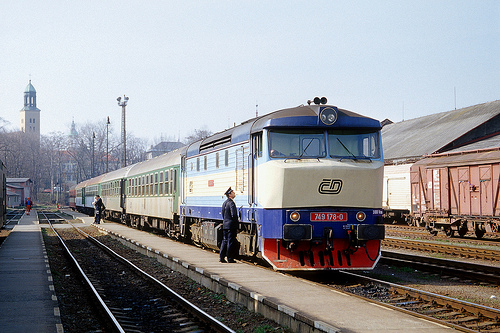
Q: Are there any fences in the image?
A: No, there are no fences.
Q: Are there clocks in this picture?
A: No, there are no clocks.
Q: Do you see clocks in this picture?
A: No, there are no clocks.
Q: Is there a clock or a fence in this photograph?
A: No, there are no clocks or fences.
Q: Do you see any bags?
A: No, there are no bags.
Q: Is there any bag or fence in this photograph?
A: No, there are no bags or fences.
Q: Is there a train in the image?
A: Yes, there is a train.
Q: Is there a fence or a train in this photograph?
A: Yes, there is a train.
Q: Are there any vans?
A: No, there are no vans.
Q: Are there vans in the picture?
A: No, there are no vans.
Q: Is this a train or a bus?
A: This is a train.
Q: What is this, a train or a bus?
A: This is a train.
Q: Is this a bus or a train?
A: This is a train.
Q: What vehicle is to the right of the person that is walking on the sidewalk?
A: The vehicle is a train.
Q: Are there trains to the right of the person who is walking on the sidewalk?
A: Yes, there is a train to the right of the person.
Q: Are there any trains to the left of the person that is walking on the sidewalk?
A: No, the train is to the right of the person.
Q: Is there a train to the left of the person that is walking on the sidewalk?
A: No, the train is to the right of the person.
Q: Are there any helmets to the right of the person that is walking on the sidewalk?
A: No, there is a train to the right of the person.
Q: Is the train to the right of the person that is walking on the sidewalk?
A: Yes, the train is to the right of the person.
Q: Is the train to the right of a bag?
A: No, the train is to the right of the person.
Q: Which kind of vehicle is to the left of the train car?
A: The vehicle is a train.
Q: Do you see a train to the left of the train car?
A: Yes, there is a train to the left of the train car.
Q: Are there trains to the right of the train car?
A: No, the train is to the left of the train car.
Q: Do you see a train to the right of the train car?
A: No, the train is to the left of the train car.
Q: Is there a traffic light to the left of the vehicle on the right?
A: No, there is a train to the left of the train car.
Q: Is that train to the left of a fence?
A: No, the train is to the left of the train car.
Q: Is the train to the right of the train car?
A: No, the train is to the left of the train car.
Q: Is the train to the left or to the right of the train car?
A: The train is to the left of the train car.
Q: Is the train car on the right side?
A: Yes, the train car is on the right of the image.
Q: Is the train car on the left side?
A: No, the train car is on the right of the image.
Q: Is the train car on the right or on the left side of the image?
A: The train car is on the right of the image.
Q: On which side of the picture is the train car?
A: The train car is on the right of the image.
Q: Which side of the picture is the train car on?
A: The train car is on the right of the image.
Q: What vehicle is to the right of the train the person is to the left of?
A: The vehicle is a train car.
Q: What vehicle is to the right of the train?
A: The vehicle is a train car.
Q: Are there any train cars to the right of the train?
A: Yes, there is a train car to the right of the train.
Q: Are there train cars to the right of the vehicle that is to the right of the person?
A: Yes, there is a train car to the right of the train.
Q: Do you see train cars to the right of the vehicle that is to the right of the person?
A: Yes, there is a train car to the right of the train.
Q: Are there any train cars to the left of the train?
A: No, the train car is to the right of the train.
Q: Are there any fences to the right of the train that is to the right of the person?
A: No, there is a train car to the right of the train.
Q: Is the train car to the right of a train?
A: Yes, the train car is to the right of a train.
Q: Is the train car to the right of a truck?
A: No, the train car is to the right of a train.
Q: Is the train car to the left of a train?
A: No, the train car is to the right of a train.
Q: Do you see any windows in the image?
A: Yes, there are windows.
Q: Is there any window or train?
A: Yes, there are windows.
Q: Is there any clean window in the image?
A: Yes, there are clean windows.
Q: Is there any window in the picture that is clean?
A: Yes, there are windows that are clean.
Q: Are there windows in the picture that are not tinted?
A: Yes, there are clean windows.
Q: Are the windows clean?
A: Yes, the windows are clean.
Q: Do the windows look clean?
A: Yes, the windows are clean.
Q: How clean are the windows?
A: The windows are clean.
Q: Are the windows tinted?
A: No, the windows are clean.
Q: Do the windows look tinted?
A: No, the windows are clean.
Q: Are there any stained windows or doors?
A: No, there are windows but they are clean.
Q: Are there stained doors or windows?
A: No, there are windows but they are clean.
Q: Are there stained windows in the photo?
A: No, there are windows but they are clean.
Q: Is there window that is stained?
A: No, there are windows but they are clean.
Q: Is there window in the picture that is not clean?
A: No, there are windows but they are clean.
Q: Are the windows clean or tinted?
A: The windows are clean.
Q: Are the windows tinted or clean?
A: The windows are clean.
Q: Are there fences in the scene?
A: No, there are no fences.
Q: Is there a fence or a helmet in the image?
A: No, there are no fences or helmets.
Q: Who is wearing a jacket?
A: The man is wearing a jacket.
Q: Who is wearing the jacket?
A: The man is wearing a jacket.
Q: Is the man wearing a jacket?
A: Yes, the man is wearing a jacket.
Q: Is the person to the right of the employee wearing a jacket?
A: Yes, the man is wearing a jacket.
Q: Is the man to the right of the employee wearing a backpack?
A: No, the man is wearing a jacket.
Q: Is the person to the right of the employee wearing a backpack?
A: No, the man is wearing a jacket.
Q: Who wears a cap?
A: The man wears a cap.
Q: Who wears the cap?
A: The man wears a cap.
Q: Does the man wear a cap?
A: Yes, the man wears a cap.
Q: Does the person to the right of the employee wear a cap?
A: Yes, the man wears a cap.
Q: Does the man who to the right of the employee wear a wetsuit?
A: No, the man wears a cap.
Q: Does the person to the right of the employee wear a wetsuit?
A: No, the man wears a cap.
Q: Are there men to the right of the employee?
A: Yes, there is a man to the right of the employee.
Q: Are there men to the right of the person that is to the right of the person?
A: Yes, there is a man to the right of the employee.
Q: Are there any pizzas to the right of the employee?
A: No, there is a man to the right of the employee.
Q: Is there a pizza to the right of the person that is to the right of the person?
A: No, there is a man to the right of the employee.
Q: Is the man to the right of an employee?
A: Yes, the man is to the right of an employee.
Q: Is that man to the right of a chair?
A: No, the man is to the right of an employee.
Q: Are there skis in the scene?
A: No, there are no skis.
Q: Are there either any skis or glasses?
A: No, there are no skis or glasses.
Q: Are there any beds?
A: No, there are no beds.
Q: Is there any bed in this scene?
A: No, there are no beds.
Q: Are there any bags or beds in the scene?
A: No, there are no beds or bags.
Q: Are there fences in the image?
A: No, there are no fences.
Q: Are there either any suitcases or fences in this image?
A: No, there are no fences or suitcases.